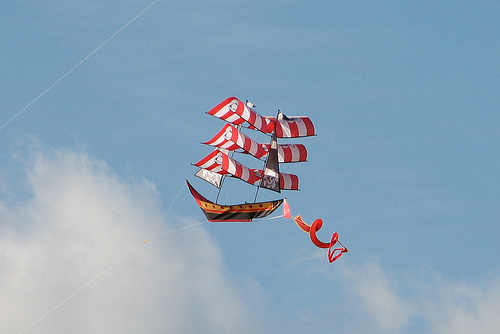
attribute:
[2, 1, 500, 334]
sky — blue, clear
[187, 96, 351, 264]
kite — red, white, ship, boat, big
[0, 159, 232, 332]
cloud — white, fluffy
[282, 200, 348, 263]
tail — red, red spiral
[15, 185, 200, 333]
string — white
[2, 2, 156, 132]
string — white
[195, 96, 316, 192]
sails — red, white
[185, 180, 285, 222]
ship — red, yellow, black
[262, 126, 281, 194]
flag — black, white